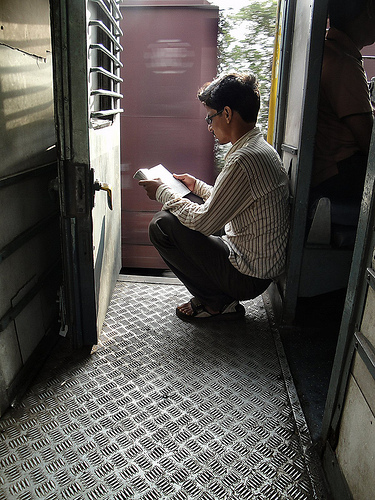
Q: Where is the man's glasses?
A: On his face.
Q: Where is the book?
A: In the man's hands.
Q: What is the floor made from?
A: Metal.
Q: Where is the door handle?
A: Attached to the door.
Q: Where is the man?
A: On a train.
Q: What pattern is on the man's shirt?
A: Stripes.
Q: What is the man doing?
A: Reading a book.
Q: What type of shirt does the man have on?
A: A striped longsleeved shirt.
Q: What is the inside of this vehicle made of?
A: It is made of aluminum metal.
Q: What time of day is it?
A: It is the afternoon.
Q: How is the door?
A: Door is open wide.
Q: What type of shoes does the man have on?
A: Open toe sandals.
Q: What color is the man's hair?
A: The man's hair is dark black.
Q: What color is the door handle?
A: The door handle is bronze.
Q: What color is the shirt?
A: Black and white.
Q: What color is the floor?
A: Silver.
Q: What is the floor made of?
A: Metal.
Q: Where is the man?
A: On the train.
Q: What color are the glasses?
A: Black.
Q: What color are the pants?
A: Gray.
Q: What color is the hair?
A: Brown.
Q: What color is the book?
A: White.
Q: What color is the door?
A: Silver.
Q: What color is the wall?
A: White.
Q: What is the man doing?
A: Reading.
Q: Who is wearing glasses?
A: Man in doorway.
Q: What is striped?
A: Shirt.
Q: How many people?
A: One.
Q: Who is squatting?
A: Man.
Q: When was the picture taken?
A: Daytime.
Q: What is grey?
A: Door.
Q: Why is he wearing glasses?
A: To see.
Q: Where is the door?
A: To the left of the man.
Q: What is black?
A: Pants.